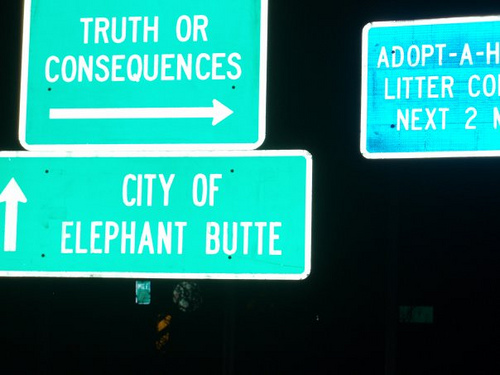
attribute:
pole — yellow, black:
[144, 312, 187, 352]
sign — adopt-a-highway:
[366, 21, 498, 154]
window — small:
[172, 17, 215, 75]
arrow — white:
[0, 174, 27, 251]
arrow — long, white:
[48, 99, 233, 128]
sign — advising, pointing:
[16, 0, 267, 151]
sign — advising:
[359, 14, 497, 160]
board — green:
[16, 4, 264, 161]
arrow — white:
[42, 96, 234, 133]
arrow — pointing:
[48, 97, 234, 126]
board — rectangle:
[38, 127, 363, 314]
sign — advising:
[357, 26, 496, 154]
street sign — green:
[359, 17, 498, 162]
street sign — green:
[16, 2, 270, 151]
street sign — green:
[3, 145, 315, 285]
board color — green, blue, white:
[366, 23, 498, 153]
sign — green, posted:
[364, 15, 496, 171]